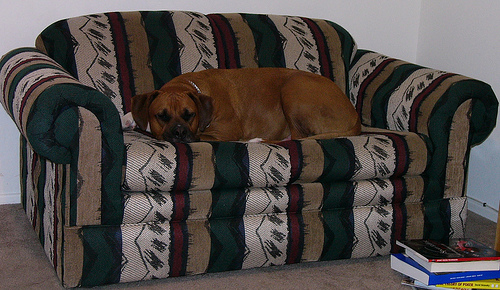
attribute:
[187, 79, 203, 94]
collar — silver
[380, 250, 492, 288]
book — blue, thick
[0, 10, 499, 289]
couch — green, red, white and brown, striped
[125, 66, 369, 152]
dog — red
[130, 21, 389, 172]
dog — brown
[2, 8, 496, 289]
loveseat — black, white, tan and red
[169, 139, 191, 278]
stripe — red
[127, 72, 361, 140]
dog — large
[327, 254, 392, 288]
carpet — grey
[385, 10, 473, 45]
white wall — blank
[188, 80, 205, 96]
chain — silver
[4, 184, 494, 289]
carpet — brown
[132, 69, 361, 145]
dog — brown